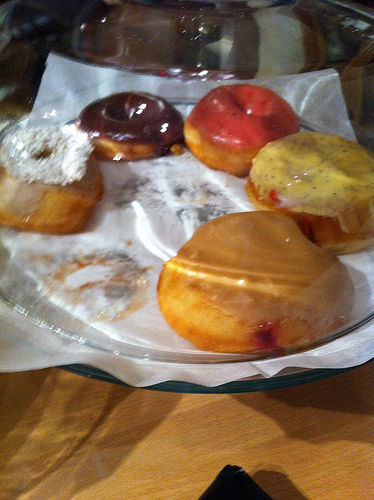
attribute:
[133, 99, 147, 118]
light — reflected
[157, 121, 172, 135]
light — reflected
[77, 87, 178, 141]
frosting — chocolate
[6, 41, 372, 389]
paper — white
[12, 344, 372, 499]
table — light brown, wood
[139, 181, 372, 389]
donut — jelly filled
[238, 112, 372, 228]
icing — yellow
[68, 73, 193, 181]
icing — chocolate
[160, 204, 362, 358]
donut — golden brown, jelly filled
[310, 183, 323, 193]
dark speck — dark 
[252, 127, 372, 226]
yellow icing — yellow 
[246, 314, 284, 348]
jelly — red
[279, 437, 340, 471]
table — brown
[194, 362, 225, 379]
paper — white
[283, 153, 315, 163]
frosting — yellow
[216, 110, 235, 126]
frosting — pink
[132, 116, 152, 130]
frosting — dark brown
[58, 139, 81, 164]
topping — white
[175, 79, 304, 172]
donut — pink , frosted 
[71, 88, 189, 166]
donut — chocolate frosted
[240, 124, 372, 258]
donut — yellow frosted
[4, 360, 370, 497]
table top — Light wood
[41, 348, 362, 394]
serving plate — large 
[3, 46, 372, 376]
wrapper paper — White 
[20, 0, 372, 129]
background — very blurry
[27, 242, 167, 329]
food stain — brown 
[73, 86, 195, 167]
ring donut — chocolate frosted